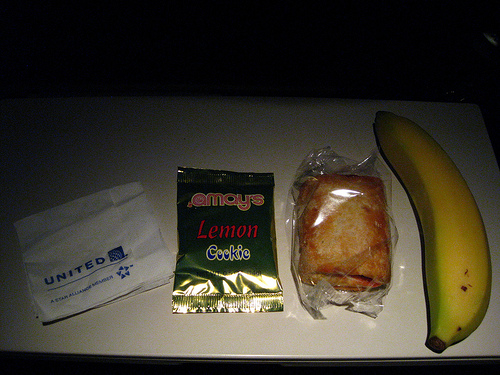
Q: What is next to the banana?
A: A small pie.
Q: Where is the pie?
A: Next to the banana.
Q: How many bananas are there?
A: One.